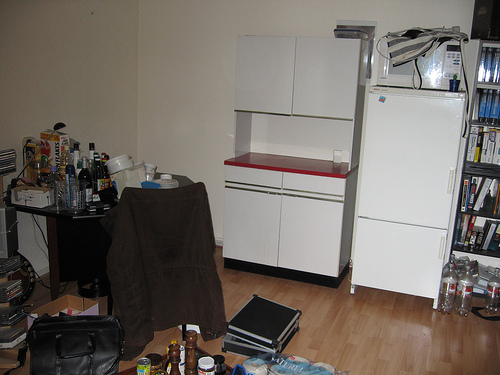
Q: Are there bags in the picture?
A: Yes, there is a bag.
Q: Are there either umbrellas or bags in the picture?
A: Yes, there is a bag.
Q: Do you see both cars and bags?
A: No, there is a bag but no cars.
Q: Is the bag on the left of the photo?
A: Yes, the bag is on the left of the image.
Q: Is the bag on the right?
A: No, the bag is on the left of the image.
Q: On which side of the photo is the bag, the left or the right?
A: The bag is on the left of the image.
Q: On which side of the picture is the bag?
A: The bag is on the left of the image.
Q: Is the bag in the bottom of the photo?
A: Yes, the bag is in the bottom of the image.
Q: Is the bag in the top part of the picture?
A: No, the bag is in the bottom of the image.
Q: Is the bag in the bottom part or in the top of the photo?
A: The bag is in the bottom of the image.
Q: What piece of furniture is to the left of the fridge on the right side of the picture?
A: The piece of furniture is a shelf.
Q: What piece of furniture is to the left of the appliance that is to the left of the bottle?
A: The piece of furniture is a shelf.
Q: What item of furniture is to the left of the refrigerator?
A: The piece of furniture is a shelf.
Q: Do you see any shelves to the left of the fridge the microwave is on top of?
A: Yes, there is a shelf to the left of the freezer.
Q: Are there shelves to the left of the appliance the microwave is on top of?
A: Yes, there is a shelf to the left of the freezer.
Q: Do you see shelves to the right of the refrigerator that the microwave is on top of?
A: No, the shelf is to the left of the freezer.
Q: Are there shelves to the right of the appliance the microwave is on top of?
A: No, the shelf is to the left of the freezer.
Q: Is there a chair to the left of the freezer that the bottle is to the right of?
A: No, there is a shelf to the left of the refrigerator.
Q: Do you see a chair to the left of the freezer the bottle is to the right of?
A: No, there is a shelf to the left of the refrigerator.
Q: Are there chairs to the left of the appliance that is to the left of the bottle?
A: No, there is a shelf to the left of the refrigerator.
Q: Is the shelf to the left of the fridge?
A: Yes, the shelf is to the left of the fridge.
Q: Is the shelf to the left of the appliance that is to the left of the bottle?
A: Yes, the shelf is to the left of the fridge.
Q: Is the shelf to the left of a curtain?
A: No, the shelf is to the left of the fridge.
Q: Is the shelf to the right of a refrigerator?
A: No, the shelf is to the left of a refrigerator.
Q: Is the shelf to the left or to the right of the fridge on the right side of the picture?
A: The shelf is to the left of the fridge.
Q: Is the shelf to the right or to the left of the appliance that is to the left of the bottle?
A: The shelf is to the left of the fridge.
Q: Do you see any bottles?
A: Yes, there is a bottle.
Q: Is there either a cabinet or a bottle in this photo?
A: Yes, there is a bottle.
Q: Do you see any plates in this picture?
A: No, there are no plates.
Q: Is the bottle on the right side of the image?
A: Yes, the bottle is on the right of the image.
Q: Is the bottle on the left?
A: No, the bottle is on the right of the image.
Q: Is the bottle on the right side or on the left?
A: The bottle is on the right of the image.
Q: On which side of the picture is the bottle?
A: The bottle is on the right of the image.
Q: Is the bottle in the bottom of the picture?
A: Yes, the bottle is in the bottom of the image.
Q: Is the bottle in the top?
A: No, the bottle is in the bottom of the image.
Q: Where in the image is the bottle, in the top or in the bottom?
A: The bottle is in the bottom of the image.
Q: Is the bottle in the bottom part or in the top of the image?
A: The bottle is in the bottom of the image.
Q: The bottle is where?
A: The bottle is on the floor.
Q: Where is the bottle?
A: The bottle is on the floor.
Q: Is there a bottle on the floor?
A: Yes, there is a bottle on the floor.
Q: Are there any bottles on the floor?
A: Yes, there is a bottle on the floor.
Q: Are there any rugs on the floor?
A: No, there is a bottle on the floor.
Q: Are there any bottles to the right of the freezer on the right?
A: Yes, there is a bottle to the right of the refrigerator.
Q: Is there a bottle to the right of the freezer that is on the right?
A: Yes, there is a bottle to the right of the refrigerator.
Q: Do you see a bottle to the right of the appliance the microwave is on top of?
A: Yes, there is a bottle to the right of the refrigerator.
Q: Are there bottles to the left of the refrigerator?
A: No, the bottle is to the right of the refrigerator.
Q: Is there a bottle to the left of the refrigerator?
A: No, the bottle is to the right of the refrigerator.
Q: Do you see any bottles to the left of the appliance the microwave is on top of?
A: No, the bottle is to the right of the refrigerator.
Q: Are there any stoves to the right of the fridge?
A: No, there is a bottle to the right of the fridge.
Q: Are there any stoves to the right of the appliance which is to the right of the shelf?
A: No, there is a bottle to the right of the fridge.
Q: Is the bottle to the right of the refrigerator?
A: Yes, the bottle is to the right of the refrigerator.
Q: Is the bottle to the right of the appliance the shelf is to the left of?
A: Yes, the bottle is to the right of the refrigerator.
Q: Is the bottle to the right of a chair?
A: No, the bottle is to the right of the refrigerator.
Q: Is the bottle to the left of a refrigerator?
A: No, the bottle is to the right of a refrigerator.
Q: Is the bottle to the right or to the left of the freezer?
A: The bottle is to the right of the freezer.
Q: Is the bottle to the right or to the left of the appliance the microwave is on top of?
A: The bottle is to the right of the freezer.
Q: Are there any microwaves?
A: Yes, there is a microwave.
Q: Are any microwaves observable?
A: Yes, there is a microwave.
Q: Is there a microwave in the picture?
A: Yes, there is a microwave.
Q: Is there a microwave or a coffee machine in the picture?
A: Yes, there is a microwave.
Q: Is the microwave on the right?
A: Yes, the microwave is on the right of the image.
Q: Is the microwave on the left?
A: No, the microwave is on the right of the image.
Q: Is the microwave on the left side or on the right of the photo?
A: The microwave is on the right of the image.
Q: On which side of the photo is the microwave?
A: The microwave is on the right of the image.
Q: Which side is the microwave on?
A: The microwave is on the right of the image.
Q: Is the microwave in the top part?
A: Yes, the microwave is in the top of the image.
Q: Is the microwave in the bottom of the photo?
A: No, the microwave is in the top of the image.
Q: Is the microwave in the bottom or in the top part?
A: The microwave is in the top of the image.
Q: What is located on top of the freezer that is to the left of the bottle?
A: The microwave is on top of the freezer.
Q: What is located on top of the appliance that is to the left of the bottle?
A: The microwave is on top of the freezer.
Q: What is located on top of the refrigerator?
A: The microwave is on top of the freezer.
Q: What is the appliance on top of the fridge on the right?
A: The appliance is a microwave.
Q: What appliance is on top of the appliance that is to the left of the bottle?
A: The appliance is a microwave.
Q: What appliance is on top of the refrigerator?
A: The appliance is a microwave.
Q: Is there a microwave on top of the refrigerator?
A: Yes, there is a microwave on top of the refrigerator.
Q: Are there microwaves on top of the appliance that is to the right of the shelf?
A: Yes, there is a microwave on top of the refrigerator.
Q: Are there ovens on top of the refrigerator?
A: No, there is a microwave on top of the refrigerator.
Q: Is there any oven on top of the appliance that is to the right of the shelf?
A: No, there is a microwave on top of the refrigerator.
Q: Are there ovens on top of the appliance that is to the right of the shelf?
A: No, there is a microwave on top of the refrigerator.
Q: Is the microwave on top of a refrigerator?
A: Yes, the microwave is on top of a refrigerator.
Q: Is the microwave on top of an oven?
A: No, the microwave is on top of a refrigerator.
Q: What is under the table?
A: The wires are under the table.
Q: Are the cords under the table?
A: Yes, the cords are under the table.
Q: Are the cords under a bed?
A: No, the cords are under the table.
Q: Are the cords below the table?
A: Yes, the cords are below the table.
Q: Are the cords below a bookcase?
A: No, the cords are below the table.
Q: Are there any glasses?
A: No, there are no glasses.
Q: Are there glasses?
A: No, there are no glasses.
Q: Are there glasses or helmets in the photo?
A: No, there are no glasses or helmets.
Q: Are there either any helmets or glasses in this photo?
A: No, there are no glasses or helmets.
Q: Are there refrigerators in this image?
A: Yes, there is a refrigerator.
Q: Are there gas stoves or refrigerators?
A: Yes, there is a refrigerator.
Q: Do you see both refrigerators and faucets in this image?
A: No, there is a refrigerator but no faucets.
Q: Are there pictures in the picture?
A: No, there are no pictures.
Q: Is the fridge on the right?
A: Yes, the fridge is on the right of the image.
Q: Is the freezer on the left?
A: No, the freezer is on the right of the image.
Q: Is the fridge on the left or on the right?
A: The fridge is on the right of the image.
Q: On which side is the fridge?
A: The fridge is on the right of the image.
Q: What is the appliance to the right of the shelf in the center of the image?
A: The appliance is a refrigerator.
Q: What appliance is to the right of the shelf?
A: The appliance is a refrigerator.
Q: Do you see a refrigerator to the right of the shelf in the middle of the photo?
A: Yes, there is a refrigerator to the right of the shelf.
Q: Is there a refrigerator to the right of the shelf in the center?
A: Yes, there is a refrigerator to the right of the shelf.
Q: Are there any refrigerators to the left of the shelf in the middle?
A: No, the refrigerator is to the right of the shelf.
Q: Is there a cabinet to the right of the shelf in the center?
A: No, there is a refrigerator to the right of the shelf.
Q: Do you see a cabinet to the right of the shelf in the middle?
A: No, there is a refrigerator to the right of the shelf.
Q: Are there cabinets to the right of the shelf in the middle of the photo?
A: No, there is a refrigerator to the right of the shelf.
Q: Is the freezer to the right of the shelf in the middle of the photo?
A: Yes, the freezer is to the right of the shelf.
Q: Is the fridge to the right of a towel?
A: No, the fridge is to the right of the shelf.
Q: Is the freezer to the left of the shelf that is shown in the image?
A: No, the freezer is to the right of the shelf.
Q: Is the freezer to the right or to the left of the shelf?
A: The freezer is to the right of the shelf.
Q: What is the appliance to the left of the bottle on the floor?
A: The appliance is a refrigerator.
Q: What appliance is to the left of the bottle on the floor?
A: The appliance is a refrigerator.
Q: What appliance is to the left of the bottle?
A: The appliance is a refrigerator.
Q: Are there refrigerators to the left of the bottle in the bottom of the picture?
A: Yes, there is a refrigerator to the left of the bottle.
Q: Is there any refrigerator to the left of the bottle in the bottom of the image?
A: Yes, there is a refrigerator to the left of the bottle.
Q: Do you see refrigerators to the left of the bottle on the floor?
A: Yes, there is a refrigerator to the left of the bottle.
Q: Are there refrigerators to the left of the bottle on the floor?
A: Yes, there is a refrigerator to the left of the bottle.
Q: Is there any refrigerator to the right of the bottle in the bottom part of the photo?
A: No, the refrigerator is to the left of the bottle.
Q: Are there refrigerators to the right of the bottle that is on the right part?
A: No, the refrigerator is to the left of the bottle.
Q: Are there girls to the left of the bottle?
A: No, there is a refrigerator to the left of the bottle.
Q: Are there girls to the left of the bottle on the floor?
A: No, there is a refrigerator to the left of the bottle.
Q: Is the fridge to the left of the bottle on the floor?
A: Yes, the fridge is to the left of the bottle.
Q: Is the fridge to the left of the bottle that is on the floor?
A: Yes, the fridge is to the left of the bottle.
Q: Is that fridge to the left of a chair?
A: No, the fridge is to the left of the bottle.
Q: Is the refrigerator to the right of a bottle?
A: No, the refrigerator is to the left of a bottle.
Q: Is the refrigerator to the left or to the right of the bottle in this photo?
A: The refrigerator is to the left of the bottle.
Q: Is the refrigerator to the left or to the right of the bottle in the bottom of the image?
A: The refrigerator is to the left of the bottle.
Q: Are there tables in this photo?
A: Yes, there is a table.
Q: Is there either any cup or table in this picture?
A: Yes, there is a table.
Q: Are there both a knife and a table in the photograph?
A: No, there is a table but no knives.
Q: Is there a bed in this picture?
A: No, there are no beds.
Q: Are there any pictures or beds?
A: No, there are no beds or pictures.